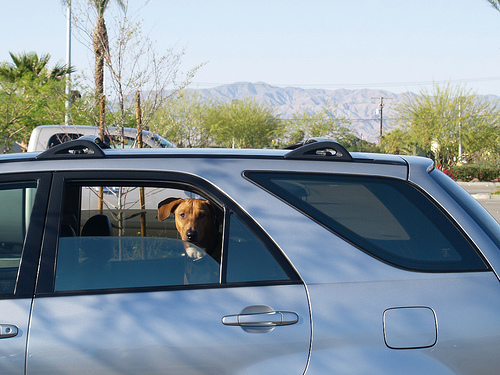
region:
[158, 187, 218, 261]
a brown dog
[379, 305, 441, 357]
the gas tank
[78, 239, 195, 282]
the glass window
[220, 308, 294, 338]
handle on th door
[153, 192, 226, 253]
dog is looking out the window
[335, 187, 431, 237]
the back window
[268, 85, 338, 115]
the mountain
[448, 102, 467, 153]
a grey pole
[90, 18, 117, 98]
a palm tree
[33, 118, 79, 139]
a grey truck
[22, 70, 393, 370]
a dog in a car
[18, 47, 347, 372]
a window down in a car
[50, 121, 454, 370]
a dog looking out a window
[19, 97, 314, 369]
a brown dog looking out a window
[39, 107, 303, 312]
a brown dog looking out car window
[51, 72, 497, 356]
a dog in a car during the day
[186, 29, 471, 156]
a mountain in the distance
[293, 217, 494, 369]
a car with a gas tank door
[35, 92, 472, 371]
a car parked with a dog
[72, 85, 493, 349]
a car with a brown dog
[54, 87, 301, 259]
a dog in the window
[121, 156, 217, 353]
a dog in the window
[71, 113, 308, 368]
a dog in the window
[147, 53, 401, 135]
mountains and a piece of sky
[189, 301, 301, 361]
a silver car door handle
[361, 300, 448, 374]
a silver door over gas tank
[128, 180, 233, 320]
dog in a car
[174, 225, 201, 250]
black nose of a dog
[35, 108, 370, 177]
black rack on top of car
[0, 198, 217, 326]
a rolled down car window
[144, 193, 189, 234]
a floppy brown dog ear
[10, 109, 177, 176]
the top of a truck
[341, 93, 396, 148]
a brown telephone pole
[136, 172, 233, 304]
A brown dog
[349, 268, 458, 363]
The opening for gas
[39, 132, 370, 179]
Luggage racks on the roof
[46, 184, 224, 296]
Two cracked windows for the dog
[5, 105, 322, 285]
A truck in the background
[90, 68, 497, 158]
Mountains in the back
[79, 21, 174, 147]
Dead palm trees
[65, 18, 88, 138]
A light post or flag pole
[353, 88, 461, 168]
Telephone poles and wires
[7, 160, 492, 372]
A silver SUV